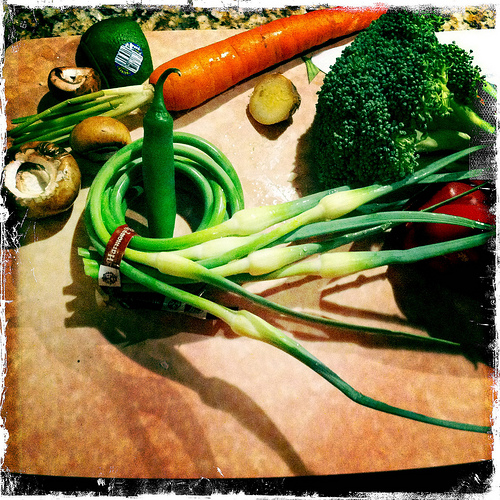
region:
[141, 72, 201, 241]
A green pepper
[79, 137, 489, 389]
A tubed green vegetable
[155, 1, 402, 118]
A large carrot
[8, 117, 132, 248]
Mushrooms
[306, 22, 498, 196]
A piece of broccoli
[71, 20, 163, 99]
A green lemon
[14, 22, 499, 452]
Ingredients for a stew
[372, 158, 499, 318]
An apple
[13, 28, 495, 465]
Vegetables sitting on a cutting board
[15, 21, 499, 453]
A multitude of vegetables sitting atop a cutting board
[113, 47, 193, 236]
GREEN JALAPENO PEPPER.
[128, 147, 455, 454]
Bunch of wild green onions.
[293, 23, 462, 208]
Bunch of broccoli.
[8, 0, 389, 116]
Orange carrot with green stem.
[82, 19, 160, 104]
Green lime with sticker.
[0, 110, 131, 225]
White Mushrooms on a table.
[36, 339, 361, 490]
Shadow on a table.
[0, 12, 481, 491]
Vegetables on a table.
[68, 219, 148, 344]
Sticker around green onions.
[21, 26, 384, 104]
An orange vegetable on a brown board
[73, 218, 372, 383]
A green vegetable on a brown board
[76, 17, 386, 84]
A carrot on a brown board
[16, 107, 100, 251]
A mushroom on a brown board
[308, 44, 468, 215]
Broccoli on a brown board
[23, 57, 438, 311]
Several vegetables on a brown board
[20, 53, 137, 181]
Mushrooms next to a carrot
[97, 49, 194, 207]
A pepper next to a carrot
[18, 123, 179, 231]
A pepper next to mushrooms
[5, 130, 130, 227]
Two mushrooms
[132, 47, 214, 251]
green jalapeno in the middle of spring onion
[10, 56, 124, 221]
three mushrooms on sheet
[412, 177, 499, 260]
red pepper on sheet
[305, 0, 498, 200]
broccoli crown on sheet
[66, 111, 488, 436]
bunch of spring onion on sheet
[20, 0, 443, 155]
one carrot on the sheet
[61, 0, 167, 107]
green pepper on sheet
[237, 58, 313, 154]
piece of ginger on sheet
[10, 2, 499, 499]
brown sheet with vegetables on it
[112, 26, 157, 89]
sticker on pepper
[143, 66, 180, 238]
Green jalapeno pepper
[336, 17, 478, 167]
fresh broccoli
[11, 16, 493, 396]
group of fresh vegetables on a counter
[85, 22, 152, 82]
green avocado with a sticker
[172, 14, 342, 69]
orange carrot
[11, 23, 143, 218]
three mushroom caps and one avocado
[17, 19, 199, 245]
green pepper, mushroom caps, and an avocado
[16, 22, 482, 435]
assortment of fresh vegetables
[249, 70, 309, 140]
section of chopped potato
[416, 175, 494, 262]
red vegetable